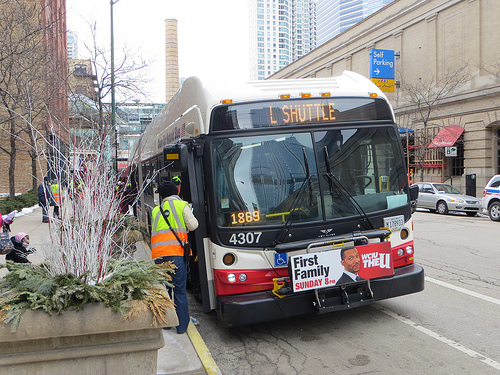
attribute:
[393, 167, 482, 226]
car — parked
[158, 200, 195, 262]
bag — black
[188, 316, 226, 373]
curb — yellow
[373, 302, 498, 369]
stripe — white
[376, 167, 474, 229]
car — parked, silver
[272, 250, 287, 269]
handicapped sign — white, blue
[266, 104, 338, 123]
light — on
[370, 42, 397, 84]
sign — blue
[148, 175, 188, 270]
vest — orange and yellow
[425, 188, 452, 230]
tire — black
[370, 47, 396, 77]
sign — blue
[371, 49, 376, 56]
letter — white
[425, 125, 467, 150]
awning — red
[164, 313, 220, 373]
street curb — yellow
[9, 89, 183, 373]
plants — potted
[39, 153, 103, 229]
people — standing